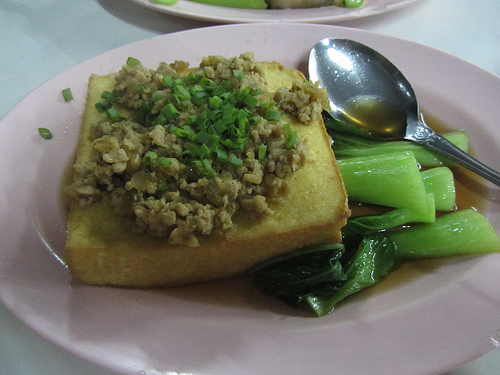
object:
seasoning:
[148, 84, 273, 187]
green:
[270, 154, 427, 333]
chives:
[30, 77, 77, 141]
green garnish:
[170, 81, 256, 163]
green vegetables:
[329, 139, 464, 263]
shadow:
[33, 305, 213, 348]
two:
[102, 50, 208, 53]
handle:
[434, 139, 481, 171]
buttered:
[164, 161, 326, 248]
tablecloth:
[14, 50, 34, 90]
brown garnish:
[102, 120, 288, 229]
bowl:
[277, 265, 472, 375]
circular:
[48, 117, 108, 375]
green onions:
[174, 85, 270, 168]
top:
[93, 167, 274, 304]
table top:
[13, 52, 43, 84]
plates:
[12, 99, 97, 318]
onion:
[210, 148, 230, 162]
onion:
[195, 139, 212, 159]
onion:
[262, 108, 281, 121]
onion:
[140, 147, 158, 166]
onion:
[160, 100, 179, 120]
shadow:
[98, 1, 222, 33]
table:
[2, 1, 484, 371]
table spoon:
[306, 36, 485, 177]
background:
[1, 1, 484, 22]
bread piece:
[60, 58, 353, 288]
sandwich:
[63, 60, 351, 288]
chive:
[202, 125, 281, 169]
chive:
[255, 95, 268, 125]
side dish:
[243, 109, 484, 318]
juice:
[155, 105, 485, 318]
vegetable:
[245, 207, 484, 317]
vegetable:
[339, 190, 438, 235]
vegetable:
[326, 129, 470, 169]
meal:
[60, 51, 485, 316]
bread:
[61, 57, 350, 287]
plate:
[128, 1, 415, 21]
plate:
[1, 20, 481, 372]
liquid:
[334, 91, 407, 141]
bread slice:
[62, 57, 352, 288]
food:
[388, 180, 441, 229]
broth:
[337, 94, 407, 143]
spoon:
[306, 36, 498, 186]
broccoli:
[315, 127, 498, 301]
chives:
[164, 72, 250, 169]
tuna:
[100, 66, 301, 236]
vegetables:
[349, 139, 448, 274]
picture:
[0, 1, 484, 371]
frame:
[209, 9, 327, 20]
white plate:
[136, 1, 419, 18]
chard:
[330, 135, 473, 313]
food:
[73, 60, 484, 301]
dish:
[1, 22, 479, 365]